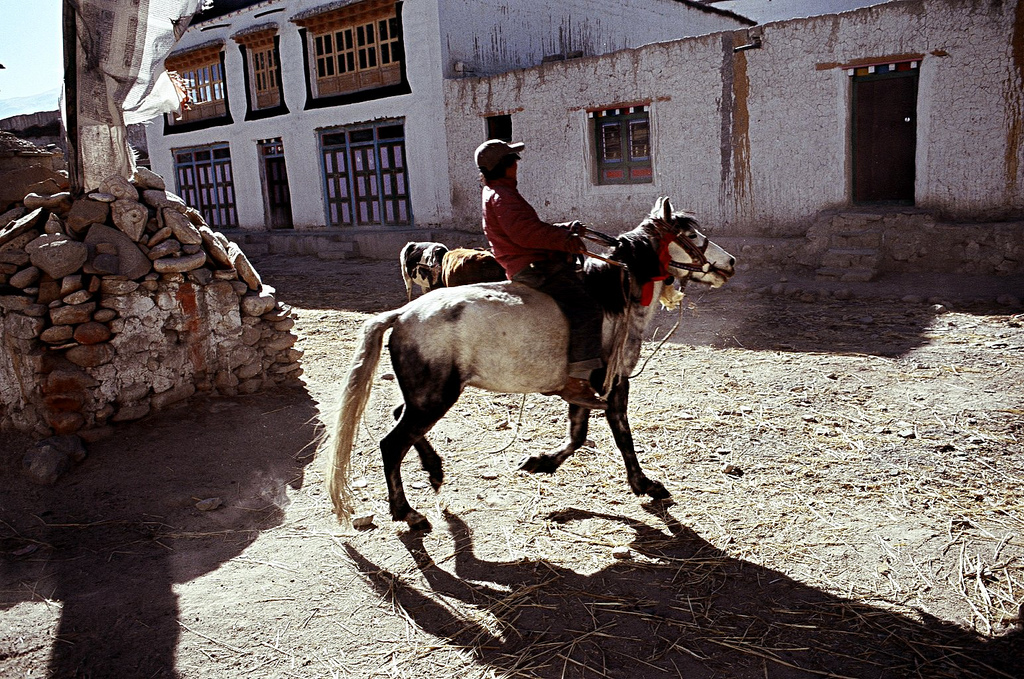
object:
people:
[471, 138, 616, 404]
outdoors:
[8, 33, 983, 558]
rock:
[38, 236, 92, 265]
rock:
[36, 238, 90, 274]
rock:
[36, 232, 101, 272]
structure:
[13, 284, 301, 416]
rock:
[27, 229, 85, 277]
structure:
[154, 36, 338, 227]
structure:
[162, 24, 313, 221]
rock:
[36, 227, 88, 271]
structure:
[165, 27, 341, 227]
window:
[299, 104, 444, 247]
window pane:
[310, 26, 332, 81]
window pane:
[367, 138, 394, 167]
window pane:
[370, 193, 397, 227]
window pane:
[239, 38, 288, 109]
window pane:
[241, 26, 280, 109]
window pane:
[161, 43, 236, 124]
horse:
[329, 197, 739, 528]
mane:
[603, 210, 699, 272]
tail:
[323, 313, 397, 523]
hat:
[472, 138, 526, 164]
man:
[474, 132, 613, 413]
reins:
[588, 212, 727, 290]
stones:
[0, 167, 299, 429]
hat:
[474, 138, 527, 170]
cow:
[442, 248, 493, 285]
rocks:
[192, 497, 233, 513]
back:
[444, 252, 471, 284]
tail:
[325, 309, 388, 532]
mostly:
[618, 401, 697, 520]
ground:
[213, 532, 986, 679]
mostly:
[559, 164, 753, 335]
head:
[626, 203, 734, 291]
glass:
[358, 106, 380, 111]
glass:
[356, 205, 391, 221]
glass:
[347, 122, 394, 145]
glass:
[362, 103, 395, 106]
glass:
[328, 203, 362, 224]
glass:
[244, 103, 272, 108]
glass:
[204, 205, 237, 225]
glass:
[599, 146, 621, 179]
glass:
[624, 123, 651, 152]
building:
[169, 49, 1024, 233]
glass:
[173, 123, 193, 152]